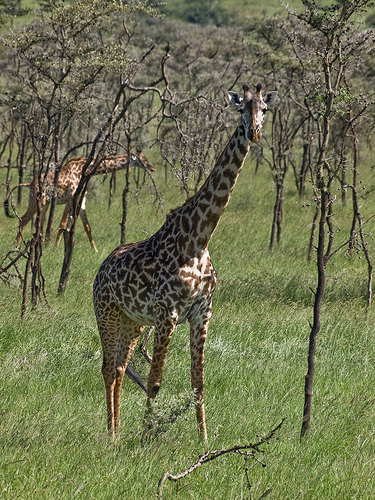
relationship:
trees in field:
[1, 0, 373, 497] [0, 0, 373, 499]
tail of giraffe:
[3, 181, 32, 219] [4, 148, 151, 253]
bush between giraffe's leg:
[136, 395, 190, 437] [145, 326, 175, 410]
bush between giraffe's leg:
[136, 395, 190, 437] [179, 323, 215, 428]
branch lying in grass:
[157, 417, 286, 495] [107, 428, 303, 497]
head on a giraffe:
[225, 85, 281, 148] [93, 84, 277, 443]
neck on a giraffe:
[187, 123, 252, 263] [39, 91, 354, 481]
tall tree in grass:
[19, 1, 57, 317] [2, 85, 372, 497]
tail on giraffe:
[4, 179, 34, 211] [25, 136, 154, 226]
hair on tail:
[3, 199, 16, 220] [3, 181, 32, 219]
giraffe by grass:
[4, 148, 151, 253] [1, 145, 373, 498]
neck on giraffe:
[187, 119, 253, 260] [87, 80, 283, 456]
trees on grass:
[1, 0, 374, 443] [57, 161, 353, 369]